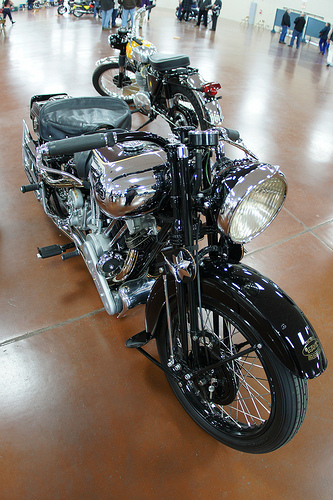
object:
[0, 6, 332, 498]
floor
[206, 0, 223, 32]
people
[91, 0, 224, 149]
bike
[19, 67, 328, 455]
bike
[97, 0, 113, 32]
people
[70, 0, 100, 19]
bike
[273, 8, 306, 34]
chalkboards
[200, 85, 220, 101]
light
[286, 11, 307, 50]
people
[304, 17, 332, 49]
boards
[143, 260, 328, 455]
tire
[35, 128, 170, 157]
handlebars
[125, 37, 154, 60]
yellow detailing